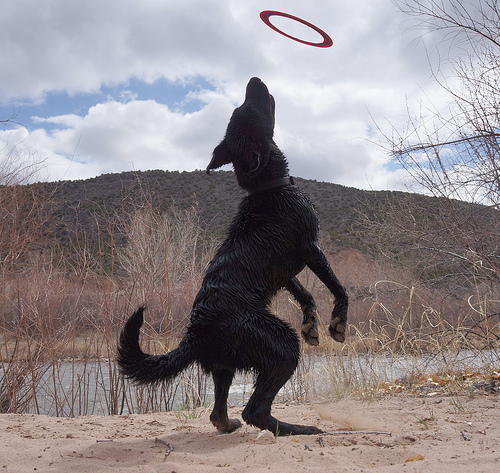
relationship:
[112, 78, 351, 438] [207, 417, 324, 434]
black dog standing on back paws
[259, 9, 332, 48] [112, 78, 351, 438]
disc headed for black dog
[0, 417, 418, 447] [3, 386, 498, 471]
tracks in sand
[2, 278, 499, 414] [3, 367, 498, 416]
stalks near edge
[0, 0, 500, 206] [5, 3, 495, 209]
blue sky has clouds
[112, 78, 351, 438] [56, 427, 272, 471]
black dog casting shadow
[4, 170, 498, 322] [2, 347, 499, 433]
mountain on other side of lake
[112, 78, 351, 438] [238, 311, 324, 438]
black dog standing on leg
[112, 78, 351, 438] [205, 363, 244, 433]
black dog standing on leg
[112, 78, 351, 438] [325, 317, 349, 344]
black dog has feet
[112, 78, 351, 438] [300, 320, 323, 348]
black dog has feet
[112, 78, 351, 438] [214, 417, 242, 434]
black dog has back paws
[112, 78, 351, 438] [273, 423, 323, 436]
black dog has feet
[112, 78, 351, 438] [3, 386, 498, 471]
black dog standing on sand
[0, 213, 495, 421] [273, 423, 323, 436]
grass beside feet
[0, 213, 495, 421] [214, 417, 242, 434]
grass beside back paws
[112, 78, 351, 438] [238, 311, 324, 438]
black dog has leg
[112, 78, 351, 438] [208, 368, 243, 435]
black dog has leg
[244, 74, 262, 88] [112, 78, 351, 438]
nose of black dog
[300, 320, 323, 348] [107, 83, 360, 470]
feet on dog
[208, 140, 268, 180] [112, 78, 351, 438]
ears of black dog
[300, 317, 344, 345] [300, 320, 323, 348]
pads of feet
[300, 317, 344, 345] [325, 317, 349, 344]
pads of feet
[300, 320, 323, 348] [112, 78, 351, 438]
feet of black dog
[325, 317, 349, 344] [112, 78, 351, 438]
feet of black dog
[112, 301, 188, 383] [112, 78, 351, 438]
tail of black dog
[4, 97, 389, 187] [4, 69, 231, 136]
puffy clouds in blue sky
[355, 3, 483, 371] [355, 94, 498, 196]
tree with branch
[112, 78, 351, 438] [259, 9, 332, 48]
black dog jumping for disc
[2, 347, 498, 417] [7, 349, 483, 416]
lake with water